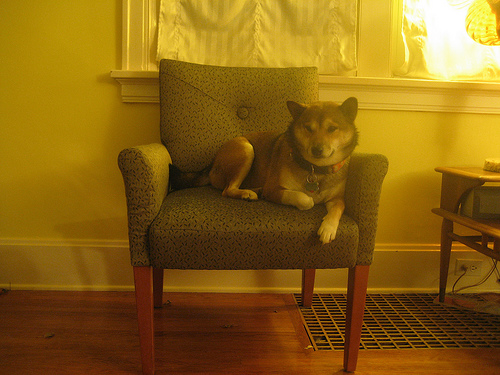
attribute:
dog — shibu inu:
[199, 91, 363, 245]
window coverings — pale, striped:
[151, 5, 365, 64]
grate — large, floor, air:
[284, 281, 481, 352]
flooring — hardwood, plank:
[5, 280, 498, 369]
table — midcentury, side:
[430, 151, 498, 311]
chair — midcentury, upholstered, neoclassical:
[118, 57, 394, 372]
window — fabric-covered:
[151, 1, 361, 81]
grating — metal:
[293, 288, 498, 353]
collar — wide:
[283, 127, 355, 177]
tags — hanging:
[302, 176, 328, 197]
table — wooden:
[426, 157, 497, 323]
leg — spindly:
[433, 219, 457, 301]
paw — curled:
[293, 190, 313, 214]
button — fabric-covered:
[230, 98, 255, 119]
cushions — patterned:
[141, 179, 372, 289]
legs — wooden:
[126, 267, 162, 373]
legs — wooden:
[301, 266, 317, 313]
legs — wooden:
[339, 260, 372, 372]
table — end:
[432, 154, 498, 331]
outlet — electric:
[454, 253, 487, 282]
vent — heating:
[293, 278, 498, 361]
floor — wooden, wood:
[7, 286, 497, 372]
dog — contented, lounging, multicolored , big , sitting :
[165, 94, 360, 244]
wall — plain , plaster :
[0, 1, 500, 294]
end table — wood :
[430, 164, 498, 304]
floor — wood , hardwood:
[0, 292, 499, 370]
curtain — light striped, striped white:
[154, 0, 360, 75]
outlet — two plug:
[454, 257, 482, 277]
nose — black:
[304, 144, 324, 158]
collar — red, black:
[282, 127, 343, 192]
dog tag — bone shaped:
[302, 167, 331, 199]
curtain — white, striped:
[150, 7, 362, 63]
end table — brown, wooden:
[432, 160, 499, 334]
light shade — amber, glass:
[462, 5, 496, 45]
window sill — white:
[101, 67, 499, 112]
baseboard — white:
[2, 238, 498, 294]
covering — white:
[157, 7, 364, 76]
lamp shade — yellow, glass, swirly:
[461, 1, 499, 46]